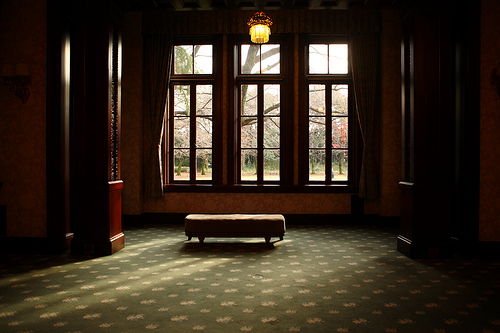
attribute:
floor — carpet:
[149, 251, 337, 332]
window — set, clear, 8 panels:
[233, 84, 292, 154]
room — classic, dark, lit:
[78, 54, 430, 332]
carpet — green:
[41, 236, 447, 330]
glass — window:
[234, 52, 284, 104]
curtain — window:
[127, 19, 198, 224]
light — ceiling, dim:
[227, 16, 280, 55]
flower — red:
[333, 129, 345, 147]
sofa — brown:
[168, 194, 281, 259]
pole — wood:
[34, 25, 135, 255]